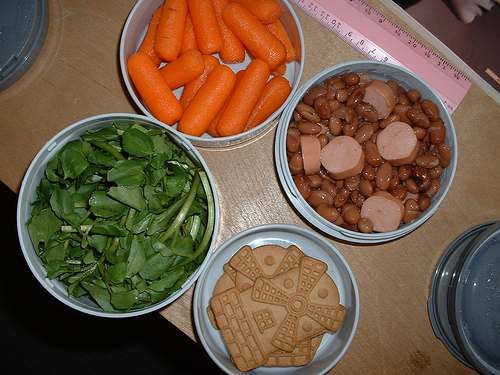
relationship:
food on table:
[107, 0, 439, 360] [0, 0, 498, 364]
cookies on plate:
[205, 242, 345, 374] [191, 222, 361, 373]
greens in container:
[44, 157, 189, 272] [10, 108, 233, 325]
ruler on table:
[306, 2, 473, 113] [0, 0, 498, 364]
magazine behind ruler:
[397, 1, 431, 16] [299, 2, 479, 122]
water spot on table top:
[410, 345, 431, 370] [4, 2, 498, 370]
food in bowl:
[286, 73, 451, 235] [272, 66, 458, 250]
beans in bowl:
[286, 73, 452, 233] [261, 62, 461, 244]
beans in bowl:
[286, 77, 453, 232] [272, 66, 458, 250]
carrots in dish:
[214, 60, 269, 141] [30, 100, 240, 327]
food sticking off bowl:
[23, 120, 217, 315] [17, 114, 221, 319]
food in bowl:
[301, 100, 422, 198] [256, 73, 445, 251]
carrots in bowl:
[127, 0, 295, 140] [234, 43, 492, 250]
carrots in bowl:
[127, 0, 295, 140] [45, 93, 216, 320]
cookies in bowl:
[205, 244, 346, 371] [187, 222, 362, 372]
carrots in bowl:
[127, 0, 295, 140] [118, 2, 305, 145]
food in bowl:
[286, 73, 451, 235] [274, 55, 466, 257]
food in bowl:
[286, 73, 451, 235] [203, 225, 354, 374]